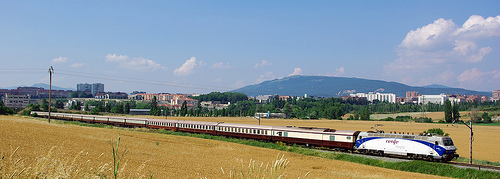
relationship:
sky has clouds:
[290, 3, 366, 49] [408, 20, 469, 62]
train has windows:
[76, 110, 466, 159] [237, 130, 255, 134]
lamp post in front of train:
[453, 117, 483, 160] [76, 110, 466, 159]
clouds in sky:
[408, 20, 469, 62] [290, 3, 366, 49]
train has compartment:
[76, 110, 466, 159] [219, 120, 271, 147]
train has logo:
[76, 110, 466, 159] [376, 138, 408, 145]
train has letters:
[76, 110, 466, 159] [387, 138, 391, 143]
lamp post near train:
[453, 117, 483, 160] [76, 110, 466, 159]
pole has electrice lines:
[48, 71, 51, 123] [60, 71, 117, 89]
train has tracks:
[76, 110, 466, 159] [465, 156, 481, 170]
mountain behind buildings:
[226, 74, 493, 97] [5, 88, 40, 111]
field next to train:
[71, 135, 115, 170] [76, 110, 466, 159]